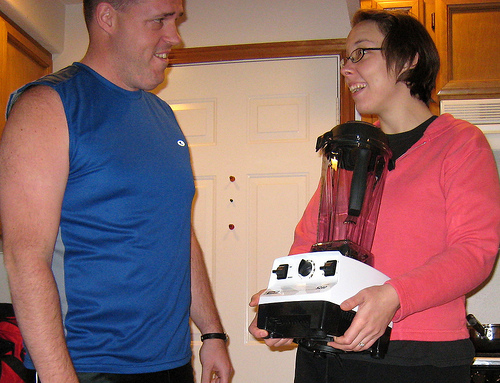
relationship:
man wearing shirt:
[2, 2, 240, 382] [10, 66, 196, 375]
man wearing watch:
[2, 2, 240, 382] [197, 330, 230, 343]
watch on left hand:
[197, 330, 230, 343] [195, 330, 236, 382]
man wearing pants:
[2, 2, 240, 382] [21, 358, 204, 382]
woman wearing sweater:
[265, 5, 497, 383] [298, 115, 499, 365]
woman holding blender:
[265, 5, 497, 383] [254, 120, 401, 356]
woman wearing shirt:
[265, 5, 497, 383] [378, 110, 435, 167]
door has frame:
[152, 53, 342, 380] [187, 41, 346, 62]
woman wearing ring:
[265, 5, 497, 383] [356, 341, 369, 349]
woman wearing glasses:
[265, 5, 497, 383] [335, 47, 382, 66]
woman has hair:
[265, 5, 497, 383] [360, 10, 444, 96]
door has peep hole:
[152, 53, 342, 380] [226, 193, 239, 205]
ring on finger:
[356, 341, 369, 349] [357, 333, 375, 356]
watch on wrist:
[197, 330, 230, 343] [197, 322, 228, 335]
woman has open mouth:
[265, 5, 497, 383] [346, 83, 370, 98]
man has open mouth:
[2, 2, 240, 382] [158, 49, 173, 64]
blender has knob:
[254, 120, 401, 356] [298, 258, 313, 274]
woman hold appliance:
[265, 5, 497, 383] [254, 120, 401, 356]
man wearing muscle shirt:
[2, 2, 240, 382] [10, 66, 196, 375]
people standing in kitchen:
[3, 5, 498, 382] [404, 3, 499, 131]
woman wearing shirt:
[265, 5, 497, 383] [10, 66, 196, 375]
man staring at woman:
[2, 2, 240, 382] [265, 5, 497, 383]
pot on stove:
[466, 310, 499, 352] [471, 343, 496, 376]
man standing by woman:
[2, 2, 240, 382] [265, 5, 497, 383]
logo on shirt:
[173, 137, 189, 149] [10, 66, 196, 375]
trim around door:
[187, 41, 346, 62] [152, 53, 342, 380]